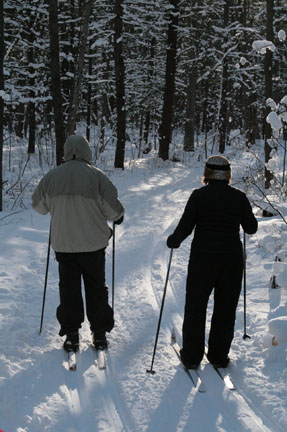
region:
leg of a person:
[52, 285, 86, 348]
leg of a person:
[77, 290, 138, 344]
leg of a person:
[160, 290, 201, 349]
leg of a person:
[209, 281, 256, 337]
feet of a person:
[57, 337, 81, 354]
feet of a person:
[78, 324, 119, 355]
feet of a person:
[177, 342, 212, 367]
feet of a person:
[195, 341, 242, 371]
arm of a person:
[24, 180, 52, 226]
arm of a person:
[96, 194, 129, 221]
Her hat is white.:
[203, 151, 230, 181]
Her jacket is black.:
[163, 182, 257, 262]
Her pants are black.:
[182, 260, 240, 373]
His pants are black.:
[50, 244, 116, 359]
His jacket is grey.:
[32, 133, 125, 251]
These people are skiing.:
[27, 121, 261, 376]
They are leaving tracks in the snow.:
[31, 367, 281, 421]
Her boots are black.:
[175, 342, 230, 367]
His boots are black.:
[58, 324, 111, 350]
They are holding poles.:
[34, 197, 120, 340]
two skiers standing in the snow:
[30, 133, 258, 369]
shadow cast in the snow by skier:
[142, 365, 226, 430]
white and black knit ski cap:
[202, 154, 232, 183]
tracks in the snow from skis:
[145, 217, 180, 324]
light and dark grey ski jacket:
[30, 133, 124, 255]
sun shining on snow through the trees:
[119, 178, 180, 308]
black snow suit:
[172, 183, 257, 367]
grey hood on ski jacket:
[61, 133, 94, 165]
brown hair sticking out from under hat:
[199, 176, 209, 186]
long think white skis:
[168, 328, 238, 393]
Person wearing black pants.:
[175, 291, 236, 325]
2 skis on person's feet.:
[172, 340, 232, 376]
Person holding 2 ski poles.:
[149, 283, 247, 333]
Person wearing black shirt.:
[201, 227, 241, 252]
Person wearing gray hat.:
[198, 153, 238, 184]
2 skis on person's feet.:
[59, 331, 120, 367]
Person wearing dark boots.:
[60, 333, 112, 348]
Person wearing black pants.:
[55, 263, 114, 317]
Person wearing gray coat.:
[67, 224, 101, 249]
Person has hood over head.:
[60, 132, 106, 167]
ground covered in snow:
[58, 348, 143, 405]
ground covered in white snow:
[63, 358, 180, 429]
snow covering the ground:
[107, 369, 223, 430]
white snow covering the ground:
[82, 354, 219, 427]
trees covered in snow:
[74, 65, 216, 126]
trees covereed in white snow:
[70, 43, 258, 155]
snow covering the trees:
[68, 84, 242, 170]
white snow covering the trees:
[89, 18, 239, 92]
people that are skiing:
[49, 176, 231, 430]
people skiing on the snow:
[30, 179, 282, 390]